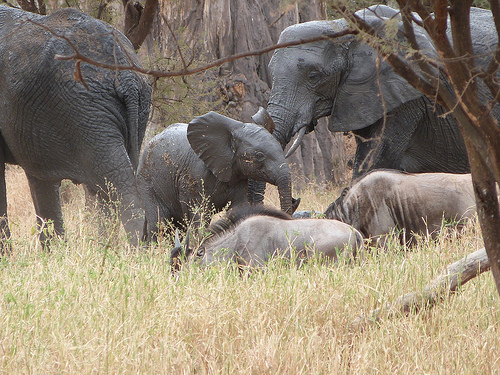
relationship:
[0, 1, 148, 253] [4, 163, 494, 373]
adult elephant on grass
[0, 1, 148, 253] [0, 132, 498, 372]
adult elephant on field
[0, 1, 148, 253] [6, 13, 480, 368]
adult elephant in area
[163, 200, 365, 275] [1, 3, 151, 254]
animal near elephant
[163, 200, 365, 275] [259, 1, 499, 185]
animal near elephant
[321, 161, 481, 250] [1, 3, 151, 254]
animal near elephant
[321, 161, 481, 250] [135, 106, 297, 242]
animal near elephant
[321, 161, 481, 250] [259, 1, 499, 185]
animal near elephant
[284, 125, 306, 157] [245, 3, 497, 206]
tusk on elephant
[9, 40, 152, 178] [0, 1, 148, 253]
wrinkled skin on adult elephant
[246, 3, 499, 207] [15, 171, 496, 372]
adult elephant are in field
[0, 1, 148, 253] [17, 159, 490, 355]
adult elephant are in field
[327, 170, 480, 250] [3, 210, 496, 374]
animal standing in grass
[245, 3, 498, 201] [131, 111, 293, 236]
adult elephant standing near baby